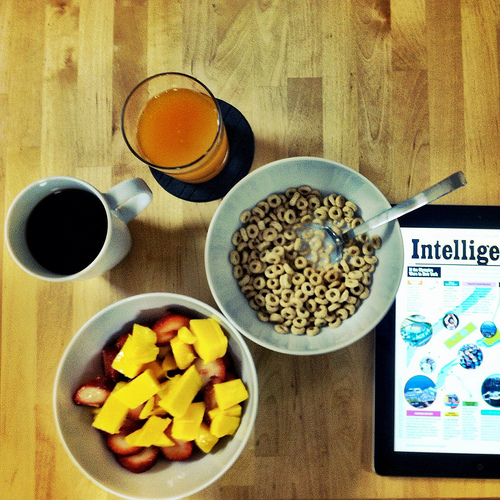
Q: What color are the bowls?
A: White.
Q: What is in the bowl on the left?
A: Mango and strawberries.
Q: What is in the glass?
A: Juice.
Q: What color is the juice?
A: Orange.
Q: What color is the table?
A: Brown.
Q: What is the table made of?
A: Wood.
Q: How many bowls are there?
A: Two.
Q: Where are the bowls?
A: On the table.